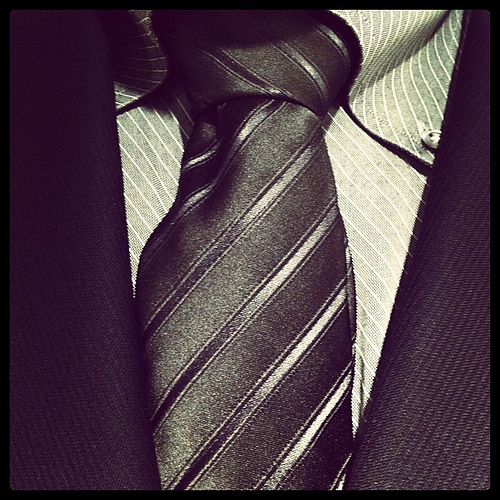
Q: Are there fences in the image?
A: No, there are no fences.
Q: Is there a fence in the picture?
A: No, there are no fences.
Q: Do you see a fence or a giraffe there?
A: No, there are no fences or giraffes.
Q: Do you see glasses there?
A: No, there are no glasses.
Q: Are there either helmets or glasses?
A: No, there are no glasses or helmets.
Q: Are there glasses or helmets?
A: No, there are no glasses or helmets.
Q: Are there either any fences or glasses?
A: No, there are no glasses or fences.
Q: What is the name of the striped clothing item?
A: The clothing item is a shirt.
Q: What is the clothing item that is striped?
A: The clothing item is a shirt.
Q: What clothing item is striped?
A: The clothing item is a shirt.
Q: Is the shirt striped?
A: Yes, the shirt is striped.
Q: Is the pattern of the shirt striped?
A: Yes, the shirt is striped.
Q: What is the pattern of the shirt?
A: The shirt is striped.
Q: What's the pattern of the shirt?
A: The shirt is striped.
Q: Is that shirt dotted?
A: No, the shirt is striped.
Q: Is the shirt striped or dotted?
A: The shirt is striped.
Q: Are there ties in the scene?
A: Yes, there is a tie.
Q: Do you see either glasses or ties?
A: Yes, there is a tie.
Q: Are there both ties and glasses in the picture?
A: No, there is a tie but no glasses.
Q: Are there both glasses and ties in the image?
A: No, there is a tie but no glasses.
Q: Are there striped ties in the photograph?
A: Yes, there is a striped tie.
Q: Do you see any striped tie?
A: Yes, there is a striped tie.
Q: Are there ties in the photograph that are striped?
A: Yes, there is a tie that is striped.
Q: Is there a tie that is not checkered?
A: Yes, there is a striped tie.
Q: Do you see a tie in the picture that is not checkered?
A: Yes, there is a striped tie.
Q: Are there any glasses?
A: No, there are no glasses.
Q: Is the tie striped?
A: Yes, the tie is striped.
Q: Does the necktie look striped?
A: Yes, the necktie is striped.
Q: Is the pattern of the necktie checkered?
A: No, the necktie is striped.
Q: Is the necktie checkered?
A: No, the necktie is striped.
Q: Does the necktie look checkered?
A: No, the necktie is striped.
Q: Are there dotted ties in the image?
A: No, there is a tie but it is striped.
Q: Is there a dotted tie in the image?
A: No, there is a tie but it is striped.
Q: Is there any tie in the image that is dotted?
A: No, there is a tie but it is striped.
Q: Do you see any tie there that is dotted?
A: No, there is a tie but it is striped.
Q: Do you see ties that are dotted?
A: No, there is a tie but it is striped.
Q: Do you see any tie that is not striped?
A: No, there is a tie but it is striped.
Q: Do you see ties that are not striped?
A: No, there is a tie but it is striped.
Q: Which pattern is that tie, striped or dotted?
A: The tie is striped.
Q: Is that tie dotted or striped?
A: The tie is striped.